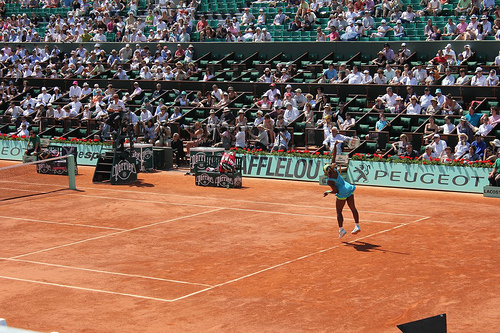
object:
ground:
[0, 183, 500, 329]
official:
[105, 94, 125, 134]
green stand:
[93, 112, 138, 184]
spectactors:
[140, 107, 153, 125]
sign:
[234, 153, 493, 194]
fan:
[323, 127, 347, 155]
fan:
[423, 145, 436, 161]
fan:
[429, 134, 447, 157]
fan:
[439, 146, 455, 163]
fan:
[454, 133, 470, 159]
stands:
[0, 0, 498, 164]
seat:
[400, 117, 412, 131]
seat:
[241, 77, 251, 81]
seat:
[293, 122, 306, 135]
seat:
[357, 124, 369, 138]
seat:
[200, 60, 208, 65]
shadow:
[342, 241, 381, 252]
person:
[247, 125, 268, 150]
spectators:
[73, 62, 84, 76]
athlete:
[323, 140, 361, 238]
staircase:
[92, 152, 137, 184]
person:
[129, 82, 142, 98]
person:
[340, 112, 355, 130]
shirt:
[327, 168, 355, 197]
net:
[0, 157, 69, 201]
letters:
[307, 160, 320, 179]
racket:
[338, 135, 361, 148]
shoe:
[338, 228, 347, 239]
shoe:
[351, 225, 361, 235]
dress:
[326, 168, 355, 200]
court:
[0, 159, 500, 333]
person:
[211, 84, 223, 101]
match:
[0, 0, 500, 333]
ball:
[324, 116, 329, 119]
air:
[231, 101, 400, 217]